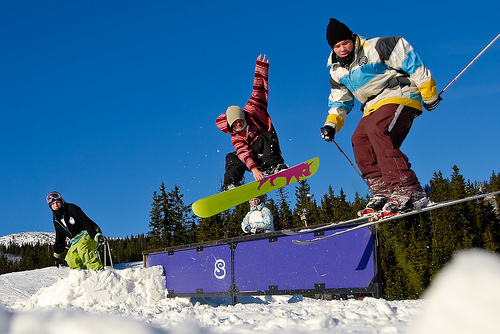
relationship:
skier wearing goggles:
[43, 187, 108, 269] [42, 188, 63, 206]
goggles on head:
[42, 188, 63, 206] [43, 189, 64, 211]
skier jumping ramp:
[272, 15, 493, 250] [28, 261, 176, 307]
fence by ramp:
[138, 215, 383, 306] [28, 261, 176, 307]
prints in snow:
[154, 287, 404, 327] [3, 259, 499, 331]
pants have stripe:
[347, 109, 421, 199] [388, 104, 403, 134]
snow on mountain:
[3, 259, 499, 331] [4, 179, 498, 331]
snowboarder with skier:
[194, 53, 323, 219] [43, 187, 108, 269]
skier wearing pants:
[43, 187, 108, 269] [60, 228, 105, 271]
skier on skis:
[272, 15, 493, 250] [280, 184, 498, 247]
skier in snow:
[43, 187, 108, 269] [3, 259, 499, 331]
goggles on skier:
[42, 188, 63, 206] [43, 187, 108, 269]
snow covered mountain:
[3, 259, 499, 331] [4, 179, 498, 331]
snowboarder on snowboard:
[194, 53, 323, 219] [189, 157, 321, 222]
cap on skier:
[323, 14, 356, 52] [272, 15, 493, 250]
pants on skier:
[60, 228, 105, 271] [43, 187, 108, 269]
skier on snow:
[43, 187, 108, 269] [3, 259, 499, 331]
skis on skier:
[280, 184, 498, 247] [272, 15, 493, 250]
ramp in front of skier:
[28, 261, 176, 307] [43, 187, 108, 269]